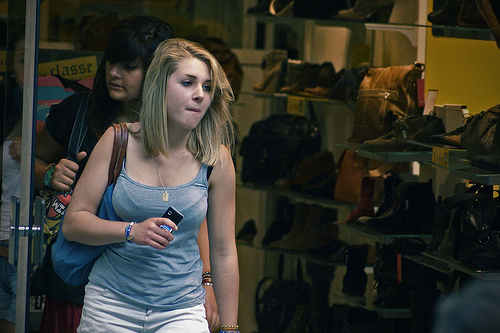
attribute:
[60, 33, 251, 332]
girl — caucasian, young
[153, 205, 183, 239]
cell phone — on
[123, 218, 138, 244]
bracelet — blue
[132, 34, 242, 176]
hair — blonde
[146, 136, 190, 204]
necklace — gold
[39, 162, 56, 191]
watch — green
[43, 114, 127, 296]
bag — blue, leather, brown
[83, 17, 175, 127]
hair — black, dark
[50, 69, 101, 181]
purse — multicolored, blue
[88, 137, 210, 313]
tank top — grey, blue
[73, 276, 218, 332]
pants — white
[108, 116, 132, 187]
strap — brown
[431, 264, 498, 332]
head — blurry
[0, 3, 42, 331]
door — open, being opened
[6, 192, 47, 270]
handle — silver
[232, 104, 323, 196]
purse — black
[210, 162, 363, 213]
shelf — glass